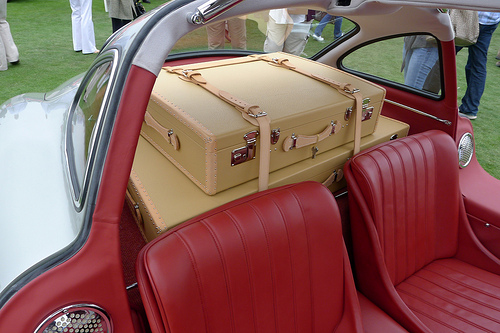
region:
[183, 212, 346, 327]
the car seat is red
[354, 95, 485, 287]
the car seat is red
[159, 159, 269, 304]
the car seat is red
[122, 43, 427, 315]
suitcases behind two red seats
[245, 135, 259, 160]
single silver suitcase latch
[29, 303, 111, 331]
top of a round silver car speaker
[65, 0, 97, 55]
bright white cotton pants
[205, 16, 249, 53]
two partial legs in khaki pants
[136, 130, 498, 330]
two red leather car seats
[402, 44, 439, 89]
single leg in blue denim jeans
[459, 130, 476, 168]
round silver car speaker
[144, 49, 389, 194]
tan leather suitcase with 2 leather straps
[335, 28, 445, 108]
glass triangle shaped window edged in black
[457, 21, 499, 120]
one leg in black pants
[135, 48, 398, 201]
yellow suitcase atop larger case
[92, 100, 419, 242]
large yellow case under smaller case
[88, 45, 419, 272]
two cases in trunk area of car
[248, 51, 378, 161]
strap holding down cases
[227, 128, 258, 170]
silver case lid latch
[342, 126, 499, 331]
red car seat on right of photo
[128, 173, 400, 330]
red car seat on left of photo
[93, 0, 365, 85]
large rear auto window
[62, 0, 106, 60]
white casual cotton pants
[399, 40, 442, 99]
blue denim jeans pants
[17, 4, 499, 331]
a red and white vehicle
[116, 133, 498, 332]
red seats in a vehicle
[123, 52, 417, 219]
luggage in a vehicle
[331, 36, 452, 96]
a window in a vehicle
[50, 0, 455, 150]
windows in a vehicle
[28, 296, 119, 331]
chrome fixture in a vehicle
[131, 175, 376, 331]
a red seat in a vehicle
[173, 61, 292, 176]
luggage strap in a vehicle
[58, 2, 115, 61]
a person wearing white pants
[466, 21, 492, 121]
a person wearing blue pants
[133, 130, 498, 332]
red seats in vehicle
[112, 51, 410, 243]
tan matching suitcases in trunk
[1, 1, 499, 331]
car has doors raised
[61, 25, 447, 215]
car has small side windows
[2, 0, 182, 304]
exterior of car is silver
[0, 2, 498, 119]
several people standing behind car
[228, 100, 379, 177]
top suitcase has metal latches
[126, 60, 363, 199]
straps have metal clips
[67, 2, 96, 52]
person has white pants and shoes on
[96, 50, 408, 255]
two suit cases are shown